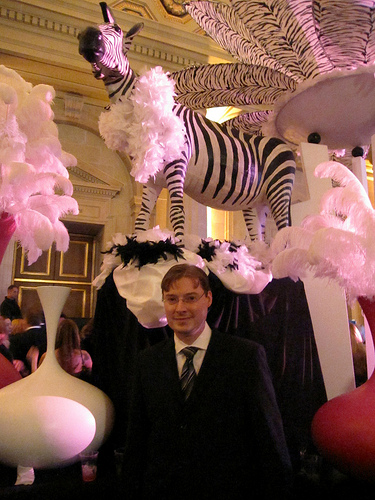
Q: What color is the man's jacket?
A: Black.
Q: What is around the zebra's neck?
A: A feather boa.